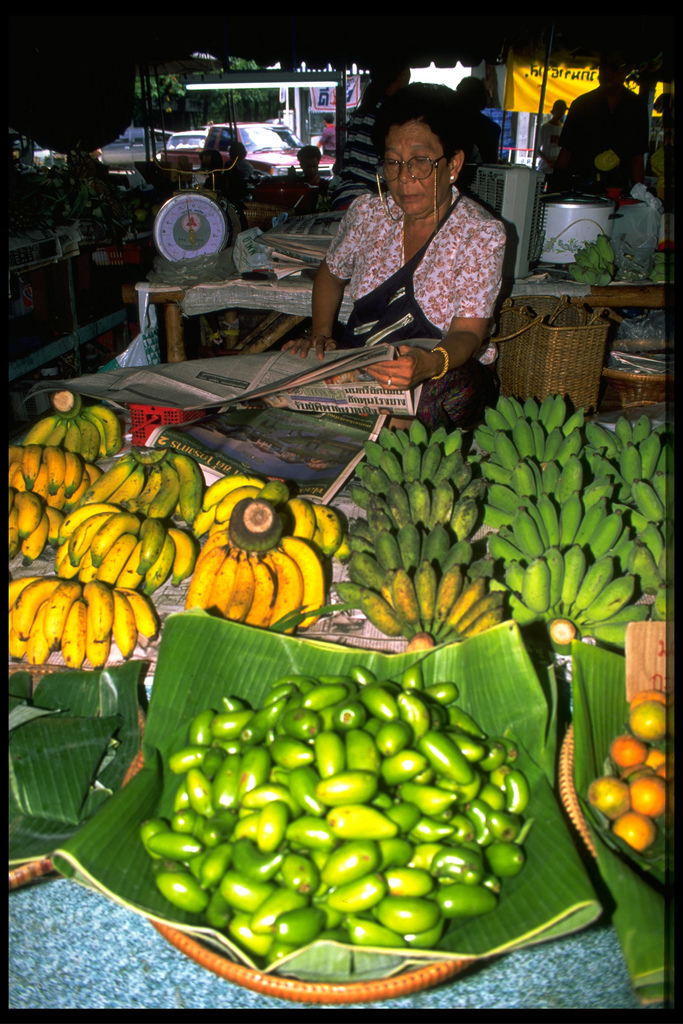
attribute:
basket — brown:
[5, 663, 154, 897]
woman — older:
[281, 80, 507, 453]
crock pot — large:
[526, 184, 622, 271]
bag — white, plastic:
[96, 285, 162, 364]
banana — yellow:
[138, 516, 165, 574]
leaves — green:
[16, 666, 135, 858]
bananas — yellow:
[72, 571, 122, 674]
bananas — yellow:
[122, 471, 231, 665]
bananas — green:
[525, 427, 615, 633]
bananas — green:
[483, 465, 615, 628]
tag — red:
[217, 355, 311, 438]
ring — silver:
[384, 344, 407, 473]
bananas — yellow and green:
[167, 501, 558, 622]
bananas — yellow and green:
[199, 463, 566, 638]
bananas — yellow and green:
[156, 476, 567, 623]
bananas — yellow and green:
[211, 481, 550, 601]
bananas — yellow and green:
[158, 451, 564, 570]